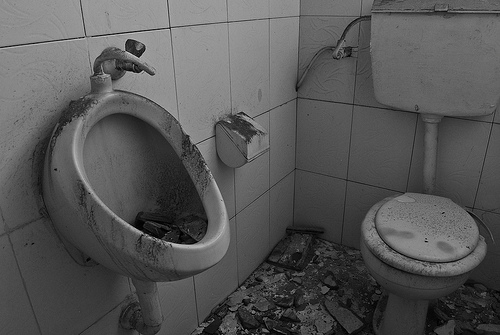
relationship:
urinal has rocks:
[39, 71, 230, 281] [137, 213, 207, 242]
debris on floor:
[197, 233, 497, 334] [192, 233, 500, 334]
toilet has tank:
[360, 191, 487, 334] [369, 0, 498, 119]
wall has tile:
[0, 2, 499, 334] [4, 3, 496, 334]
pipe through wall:
[117, 277, 164, 334] [0, 2, 499, 334]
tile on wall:
[4, 3, 496, 334] [0, 2, 499, 334]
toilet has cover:
[360, 191, 487, 334] [375, 193, 479, 262]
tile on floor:
[194, 230, 499, 334] [192, 233, 500, 334]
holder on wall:
[216, 112, 268, 170] [0, 2, 499, 334]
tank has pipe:
[369, 0, 498, 119] [420, 113, 441, 194]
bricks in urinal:
[137, 213, 207, 242] [39, 71, 230, 281]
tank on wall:
[369, 0, 498, 119] [0, 2, 499, 334]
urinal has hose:
[39, 71, 230, 281] [92, 41, 155, 91]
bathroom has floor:
[3, 2, 497, 331] [192, 233, 500, 334]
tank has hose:
[369, 0, 498, 119] [295, 15, 370, 86]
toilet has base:
[360, 191, 487, 334] [379, 291, 430, 334]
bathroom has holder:
[3, 2, 497, 331] [216, 112, 268, 170]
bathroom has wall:
[3, 2, 497, 331] [0, 2, 499, 334]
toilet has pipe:
[360, 191, 487, 334] [420, 113, 441, 194]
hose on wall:
[295, 15, 370, 86] [0, 2, 499, 334]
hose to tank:
[295, 15, 370, 86] [369, 0, 498, 119]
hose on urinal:
[92, 41, 155, 91] [39, 71, 230, 281]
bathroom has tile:
[3, 2, 497, 331] [4, 3, 496, 334]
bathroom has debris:
[3, 2, 497, 331] [197, 233, 497, 334]